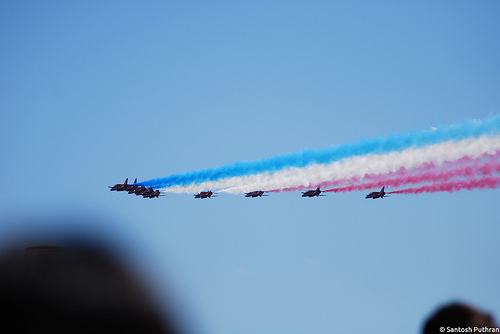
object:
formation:
[105, 176, 388, 199]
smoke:
[383, 175, 498, 194]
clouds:
[0, 0, 500, 333]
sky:
[0, 0, 500, 332]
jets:
[193, 189, 215, 200]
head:
[0, 245, 174, 332]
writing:
[437, 324, 499, 334]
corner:
[471, 311, 499, 333]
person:
[0, 243, 167, 333]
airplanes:
[364, 186, 389, 200]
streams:
[323, 160, 499, 192]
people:
[420, 298, 500, 333]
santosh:
[446, 325, 468, 334]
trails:
[213, 146, 500, 196]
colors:
[134, 116, 499, 189]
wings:
[156, 194, 159, 198]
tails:
[381, 184, 386, 194]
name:
[443, 325, 499, 334]